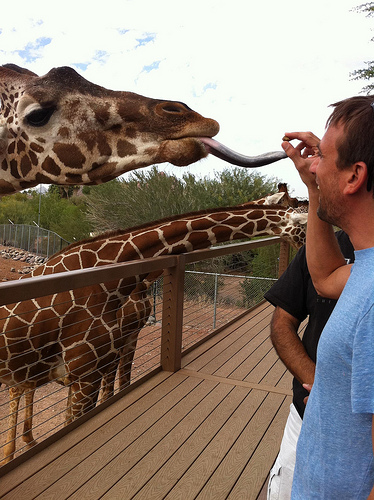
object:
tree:
[238, 241, 278, 310]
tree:
[198, 271, 219, 302]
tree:
[58, 202, 90, 242]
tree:
[0, 189, 40, 251]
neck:
[102, 203, 286, 314]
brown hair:
[324, 97, 373, 199]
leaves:
[348, 0, 373, 96]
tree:
[84, 164, 199, 233]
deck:
[0, 300, 310, 499]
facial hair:
[313, 177, 353, 233]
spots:
[50, 141, 87, 171]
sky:
[0, 0, 373, 201]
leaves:
[131, 172, 150, 183]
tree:
[217, 167, 279, 264]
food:
[280, 132, 292, 144]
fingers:
[279, 141, 306, 177]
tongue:
[181, 135, 288, 169]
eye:
[21, 105, 52, 128]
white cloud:
[0, 0, 373, 198]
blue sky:
[10, 36, 53, 64]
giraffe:
[0, 199, 308, 468]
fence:
[0, 236, 290, 474]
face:
[307, 116, 347, 228]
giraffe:
[0, 63, 287, 198]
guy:
[266, 229, 355, 499]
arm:
[269, 256, 316, 386]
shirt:
[262, 229, 354, 421]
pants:
[264, 403, 303, 499]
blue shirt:
[289, 248, 373, 498]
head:
[0, 62, 288, 197]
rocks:
[141, 315, 157, 327]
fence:
[0, 218, 70, 259]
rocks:
[9, 265, 17, 272]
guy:
[278, 95, 374, 499]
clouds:
[0, 0, 373, 201]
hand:
[280, 130, 330, 191]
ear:
[342, 160, 366, 197]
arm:
[304, 190, 355, 298]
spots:
[156, 218, 189, 247]